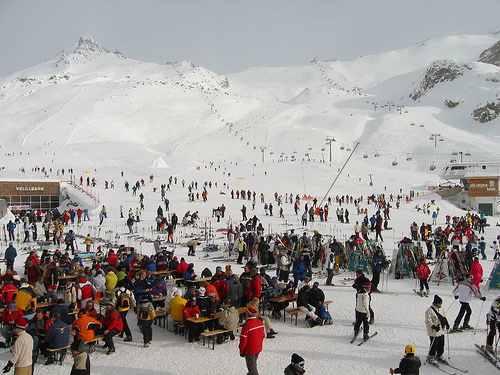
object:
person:
[227, 273, 233, 285]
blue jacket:
[223, 268, 238, 289]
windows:
[16, 196, 29, 203]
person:
[179, 295, 199, 317]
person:
[201, 291, 221, 307]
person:
[1, 241, 17, 273]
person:
[307, 280, 332, 327]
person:
[267, 279, 285, 293]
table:
[182, 307, 261, 339]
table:
[266, 288, 297, 321]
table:
[144, 291, 169, 313]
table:
[35, 294, 61, 314]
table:
[149, 264, 183, 282]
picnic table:
[186, 307, 241, 346]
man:
[38, 311, 70, 365]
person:
[65, 306, 102, 361]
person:
[0, 277, 20, 309]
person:
[203, 279, 221, 306]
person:
[413, 258, 430, 293]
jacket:
[415, 261, 430, 280]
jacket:
[69, 314, 100, 341]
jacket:
[204, 285, 216, 302]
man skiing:
[201, 101, 316, 185]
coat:
[238, 316, 262, 357]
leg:
[361, 319, 369, 341]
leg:
[353, 313, 359, 338]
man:
[352, 280, 373, 343]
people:
[412, 255, 433, 298]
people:
[466, 257, 487, 294]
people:
[168, 289, 189, 330]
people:
[95, 300, 128, 355]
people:
[156, 207, 165, 222]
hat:
[244, 304, 260, 319]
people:
[65, 345, 95, 375]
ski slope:
[1, 34, 498, 374]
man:
[237, 308, 265, 375]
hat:
[429, 293, 442, 303]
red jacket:
[415, 261, 431, 284]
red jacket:
[235, 315, 271, 358]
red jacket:
[469, 262, 486, 280]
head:
[245, 304, 259, 314]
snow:
[0, 33, 499, 375]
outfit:
[352, 289, 372, 339]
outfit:
[425, 304, 449, 358]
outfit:
[238, 317, 266, 374]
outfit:
[8, 332, 35, 374]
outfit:
[136, 302, 157, 345]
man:
[423, 291, 449, 364]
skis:
[348, 322, 385, 348]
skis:
[427, 344, 467, 375]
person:
[42, 312, 77, 356]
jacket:
[354, 281, 369, 340]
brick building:
[0, 172, 62, 222]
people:
[388, 345, 422, 375]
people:
[451, 269, 486, 334]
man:
[74, 308, 102, 355]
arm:
[238, 324, 249, 352]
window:
[38, 191, 53, 203]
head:
[289, 350, 303, 371]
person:
[281, 351, 304, 375]